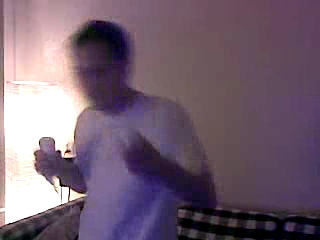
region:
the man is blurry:
[28, 24, 219, 236]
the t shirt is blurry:
[70, 97, 205, 235]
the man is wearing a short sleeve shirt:
[69, 100, 203, 238]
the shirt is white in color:
[70, 99, 207, 237]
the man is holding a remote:
[117, 124, 146, 170]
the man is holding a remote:
[35, 135, 63, 187]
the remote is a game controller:
[38, 135, 66, 187]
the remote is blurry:
[116, 129, 138, 152]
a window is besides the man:
[2, 2, 136, 225]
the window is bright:
[1, 77, 102, 223]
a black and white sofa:
[186, 215, 319, 239]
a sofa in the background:
[13, 191, 313, 234]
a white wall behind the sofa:
[218, 93, 283, 181]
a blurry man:
[29, 20, 212, 232]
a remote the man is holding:
[38, 133, 64, 180]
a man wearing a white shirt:
[55, 31, 184, 227]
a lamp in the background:
[6, 84, 76, 142]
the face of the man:
[71, 30, 121, 100]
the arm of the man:
[134, 132, 175, 178]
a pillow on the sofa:
[35, 213, 70, 236]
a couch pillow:
[213, 215, 258, 238]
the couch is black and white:
[222, 209, 259, 234]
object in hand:
[37, 135, 58, 156]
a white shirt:
[92, 195, 139, 235]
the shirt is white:
[90, 165, 127, 220]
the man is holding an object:
[37, 135, 61, 156]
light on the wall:
[28, 95, 68, 126]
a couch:
[201, 215, 278, 234]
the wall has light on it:
[18, 95, 56, 119]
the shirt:
[90, 141, 122, 199]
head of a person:
[60, 22, 148, 110]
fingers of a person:
[32, 147, 53, 179]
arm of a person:
[31, 139, 89, 194]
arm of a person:
[131, 139, 225, 215]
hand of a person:
[121, 129, 156, 172]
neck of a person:
[101, 89, 139, 118]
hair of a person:
[69, 9, 141, 49]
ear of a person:
[112, 56, 138, 83]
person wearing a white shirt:
[22, 19, 227, 237]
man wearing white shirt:
[29, 0, 224, 239]